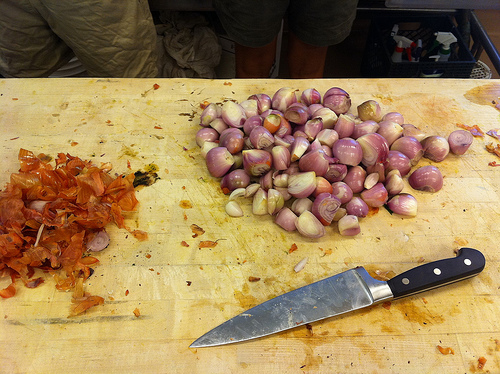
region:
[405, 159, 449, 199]
small piece of cut shallot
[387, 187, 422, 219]
small piece of cut shallot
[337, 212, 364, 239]
small piece of cut shallot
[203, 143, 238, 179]
small piece of cut shallot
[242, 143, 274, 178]
small piece of cut shallot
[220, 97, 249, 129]
small piece of cut shallot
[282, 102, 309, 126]
small piece of cut shallot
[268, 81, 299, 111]
small piece of cut shallot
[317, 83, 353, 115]
small piece of cut shallot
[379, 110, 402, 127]
small piece of cut shallot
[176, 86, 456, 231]
These onions are purple but called red onions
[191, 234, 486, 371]
A large knife for chopping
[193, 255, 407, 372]
The knife is sharp metal blade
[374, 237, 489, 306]
The handle is black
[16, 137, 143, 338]
The skins from the onions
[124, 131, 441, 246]
Small onions laying on a cutting board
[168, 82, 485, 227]
A pile of onions that have no skins or stems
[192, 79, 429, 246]
A pile of onions ready to be chopped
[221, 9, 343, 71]
The legs of a person in gray shorts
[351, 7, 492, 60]
A container holding cleaning produts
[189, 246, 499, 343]
this is a knife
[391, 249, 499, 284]
the handle is black in color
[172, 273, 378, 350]
the knife is sharp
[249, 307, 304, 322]
the area is metallic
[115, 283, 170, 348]
this is a table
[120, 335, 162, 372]
the table is wooden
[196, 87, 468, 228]
these are several onions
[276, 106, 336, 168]
the onions are purple in color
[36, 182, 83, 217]
these are some spices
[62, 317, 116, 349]
the board is brown in color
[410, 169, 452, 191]
chopped onion on cutting board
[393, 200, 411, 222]
chopped onion on cutting board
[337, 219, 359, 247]
chopped onion on cutting board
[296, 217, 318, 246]
chopped onion on cutting board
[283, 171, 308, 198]
chopped onion on cutting board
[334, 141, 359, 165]
chopped onion on cutting board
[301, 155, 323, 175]
chopped onion on cutting board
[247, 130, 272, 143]
chopped onion on cutting board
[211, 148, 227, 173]
chopped onion on cutting board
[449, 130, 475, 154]
chopped onion on cutting board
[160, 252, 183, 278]
part of a line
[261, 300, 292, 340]
part of a knife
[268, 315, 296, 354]
part of a knife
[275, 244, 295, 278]
part of a onion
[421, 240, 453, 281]
part of a handle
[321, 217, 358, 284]
part of an onion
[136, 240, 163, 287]
part of a board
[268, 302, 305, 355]
part of an edge